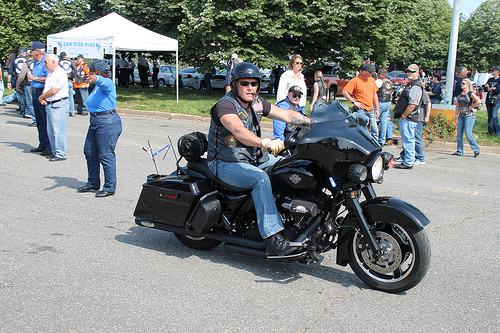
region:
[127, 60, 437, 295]
Man and black motorcyle on the road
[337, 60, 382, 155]
Man in orange shirt and black hat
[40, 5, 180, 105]
White shade canopy on the grass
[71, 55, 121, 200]
Woman in blue jeans and blue shirt pointing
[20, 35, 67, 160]
Two older men on the left standing together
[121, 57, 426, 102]
Parked cars in the background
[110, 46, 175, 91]
Group of people standing under the canopy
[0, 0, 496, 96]
Green trees in the background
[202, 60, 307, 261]
Man wearing a helmet riding the motorcycle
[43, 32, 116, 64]
White sign with blue writing on the canopy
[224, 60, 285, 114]
Man wearing black helmet.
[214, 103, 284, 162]
Man wearing dark vest.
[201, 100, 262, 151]
Man wearing black t-shirt.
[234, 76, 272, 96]
Sunglasses on man's face.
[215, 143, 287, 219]
Man wearing blue jeans.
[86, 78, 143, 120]
Person wearing blue shirt.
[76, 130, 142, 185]
Person wearing blue jeans.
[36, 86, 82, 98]
Person wearing white shirt.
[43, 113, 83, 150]
Person wearing blue jeans.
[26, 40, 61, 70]
Blue hat on man's head.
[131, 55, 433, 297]
man riding black motorcycle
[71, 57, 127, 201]
woman wearing blue shirt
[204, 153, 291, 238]
blue jeans of motorcyclist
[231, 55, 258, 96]
black helmet of man on the motorcycle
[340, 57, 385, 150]
man wearing orange shirt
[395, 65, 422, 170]
man wearing black vest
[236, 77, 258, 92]
black sunglasses motorcyclist is wearing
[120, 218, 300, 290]
shadow of motorcycle on payment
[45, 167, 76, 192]
shadow of woman in blue shirt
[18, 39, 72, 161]
two older men standing together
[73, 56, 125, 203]
woman is pointing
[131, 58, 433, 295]
man is riding a motorcycle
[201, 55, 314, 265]
rider is wearing a black helmet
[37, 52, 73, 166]
an elderly man wearing a white shirt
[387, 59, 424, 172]
an onlooker wears a baseball cap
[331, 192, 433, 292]
front wheel of a motorcycle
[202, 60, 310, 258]
rider wears blue jeans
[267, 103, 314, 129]
motorcyclist has a tattoo'd arm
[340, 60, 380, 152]
man wears a bright orange shirt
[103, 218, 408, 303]
shadow of a motorcycle on the ground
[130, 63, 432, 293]
Man riding a motorcycle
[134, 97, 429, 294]
The motorcycle is black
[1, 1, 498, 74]
Green trees in background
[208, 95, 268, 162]
Man wearing a vest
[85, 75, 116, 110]
The shirt is blue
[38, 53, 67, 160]
Old man in street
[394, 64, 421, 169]
Man looking to his left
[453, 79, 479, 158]
A woman is walking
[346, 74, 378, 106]
The shirt is orange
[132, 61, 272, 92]
Cars are parked